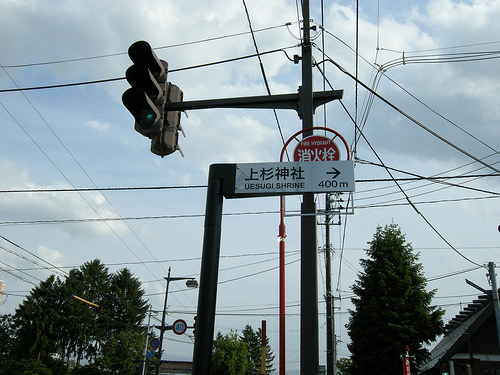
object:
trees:
[0, 256, 151, 374]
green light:
[139, 110, 157, 127]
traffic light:
[121, 40, 188, 159]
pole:
[193, 178, 222, 373]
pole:
[298, 0, 321, 374]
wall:
[255, 67, 356, 103]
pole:
[278, 196, 285, 375]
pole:
[325, 193, 337, 374]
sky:
[0, 0, 500, 375]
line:
[0, 24, 286, 68]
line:
[241, 0, 291, 162]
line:
[0, 173, 500, 195]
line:
[341, 149, 500, 208]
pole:
[261, 320, 267, 375]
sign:
[235, 160, 356, 192]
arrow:
[326, 167, 341, 179]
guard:
[71, 294, 99, 307]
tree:
[336, 217, 448, 374]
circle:
[280, 127, 350, 162]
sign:
[292, 135, 341, 162]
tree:
[211, 323, 277, 375]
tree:
[99, 329, 160, 375]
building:
[414, 288, 499, 374]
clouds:
[27, 110, 141, 203]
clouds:
[116, 4, 309, 66]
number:
[175, 324, 183, 331]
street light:
[185, 279, 197, 288]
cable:
[380, 40, 499, 50]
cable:
[350, 51, 499, 172]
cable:
[0, 44, 300, 93]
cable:
[151, 265, 484, 312]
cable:
[0, 64, 197, 316]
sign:
[172, 319, 187, 335]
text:
[245, 166, 305, 180]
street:
[0, 295, 497, 373]